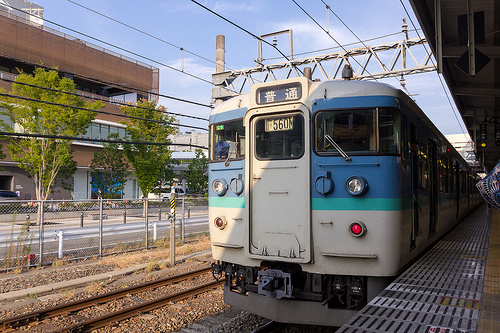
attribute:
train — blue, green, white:
[212, 81, 489, 317]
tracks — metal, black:
[24, 255, 281, 332]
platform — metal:
[382, 196, 500, 326]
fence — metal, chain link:
[0, 199, 212, 245]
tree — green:
[7, 73, 94, 255]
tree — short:
[124, 104, 168, 194]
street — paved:
[7, 194, 203, 236]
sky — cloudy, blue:
[72, 7, 445, 94]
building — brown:
[3, 22, 162, 205]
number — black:
[265, 118, 298, 130]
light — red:
[351, 221, 364, 235]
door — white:
[251, 113, 309, 261]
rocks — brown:
[145, 304, 189, 332]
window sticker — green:
[212, 125, 228, 130]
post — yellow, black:
[166, 180, 179, 266]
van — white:
[144, 179, 179, 201]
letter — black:
[287, 117, 295, 128]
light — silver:
[347, 178, 364, 195]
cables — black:
[5, 128, 205, 150]